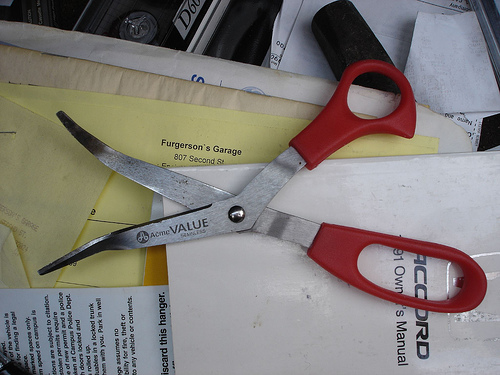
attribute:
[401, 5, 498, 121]
paper — white, folded over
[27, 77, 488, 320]
scissors — metal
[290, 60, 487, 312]
handles — red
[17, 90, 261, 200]
paper — yellow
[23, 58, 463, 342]
scissors — open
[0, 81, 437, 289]
receipt — yellow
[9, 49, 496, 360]
scissors — pair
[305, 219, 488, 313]
handle — red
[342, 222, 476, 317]
opening — small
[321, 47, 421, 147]
opening — big